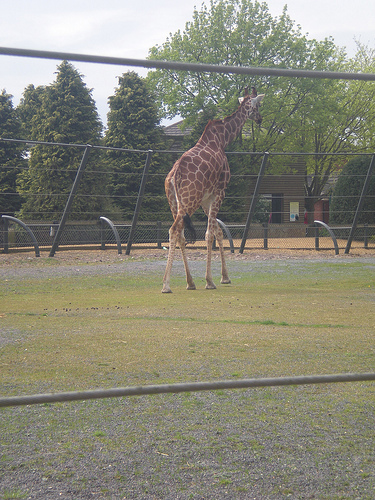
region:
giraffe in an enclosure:
[128, 82, 264, 290]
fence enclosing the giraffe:
[8, 125, 363, 261]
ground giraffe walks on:
[7, 255, 360, 489]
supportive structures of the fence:
[20, 210, 356, 264]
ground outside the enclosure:
[256, 234, 338, 243]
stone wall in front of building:
[329, 220, 373, 240]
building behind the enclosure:
[161, 97, 340, 218]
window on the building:
[259, 194, 281, 221]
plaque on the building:
[289, 199, 300, 223]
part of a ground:
[193, 436, 219, 472]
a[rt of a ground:
[127, 415, 168, 471]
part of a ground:
[176, 435, 200, 465]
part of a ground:
[195, 425, 214, 446]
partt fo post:
[215, 359, 234, 382]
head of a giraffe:
[233, 78, 272, 128]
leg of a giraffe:
[151, 213, 196, 284]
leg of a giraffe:
[212, 226, 250, 272]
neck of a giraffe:
[206, 108, 254, 150]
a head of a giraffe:
[233, 78, 280, 125]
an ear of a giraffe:
[246, 87, 266, 107]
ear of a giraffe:
[253, 93, 267, 104]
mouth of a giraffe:
[254, 113, 267, 124]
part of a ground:
[204, 458, 225, 487]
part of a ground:
[211, 397, 234, 424]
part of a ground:
[214, 450, 236, 478]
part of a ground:
[234, 455, 253, 478]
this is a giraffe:
[166, 85, 248, 322]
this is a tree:
[45, 57, 98, 176]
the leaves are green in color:
[43, 93, 81, 137]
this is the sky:
[74, 9, 142, 57]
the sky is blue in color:
[75, 6, 171, 63]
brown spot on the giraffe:
[180, 175, 191, 190]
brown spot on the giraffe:
[191, 163, 203, 185]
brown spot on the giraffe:
[191, 175, 202, 195]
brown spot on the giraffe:
[205, 137, 216, 155]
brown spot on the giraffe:
[204, 125, 216, 145]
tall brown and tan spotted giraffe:
[142, 62, 272, 300]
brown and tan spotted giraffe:
[144, 71, 273, 294]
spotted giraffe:
[168, 84, 276, 306]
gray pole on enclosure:
[48, 42, 93, 74]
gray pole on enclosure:
[98, 212, 125, 254]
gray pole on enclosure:
[10, 212, 50, 269]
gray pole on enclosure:
[67, 132, 154, 207]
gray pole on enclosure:
[248, 144, 300, 222]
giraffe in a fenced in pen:
[1, 45, 372, 498]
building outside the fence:
[141, 87, 363, 240]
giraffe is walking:
[154, 85, 269, 293]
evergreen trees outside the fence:
[0, 60, 169, 228]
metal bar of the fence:
[1, 44, 374, 86]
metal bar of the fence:
[0, 368, 372, 408]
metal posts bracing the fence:
[44, 136, 157, 262]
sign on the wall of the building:
[287, 196, 302, 226]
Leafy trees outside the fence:
[138, 2, 372, 251]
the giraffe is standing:
[162, 84, 264, 292]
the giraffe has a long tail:
[161, 84, 264, 294]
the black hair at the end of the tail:
[172, 165, 196, 244]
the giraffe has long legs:
[161, 84, 265, 294]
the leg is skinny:
[204, 189, 223, 287]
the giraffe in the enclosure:
[0, 44, 373, 498]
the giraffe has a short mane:
[160, 84, 264, 291]